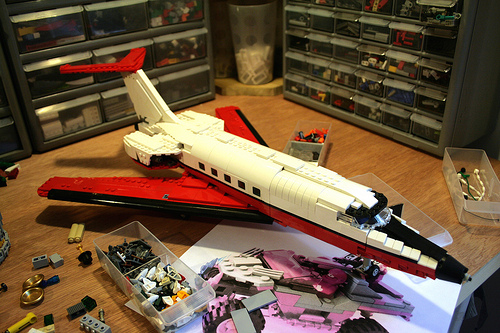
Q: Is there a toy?
A: Yes, there is a toy.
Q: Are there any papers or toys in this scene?
A: Yes, there is a toy.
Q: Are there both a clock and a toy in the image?
A: No, there is a toy but no clocks.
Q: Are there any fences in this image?
A: No, there are no fences.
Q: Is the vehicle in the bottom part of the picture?
A: Yes, the vehicle is in the bottom of the image.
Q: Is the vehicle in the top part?
A: No, the vehicle is in the bottom of the image.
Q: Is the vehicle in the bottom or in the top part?
A: The vehicle is in the bottom of the image.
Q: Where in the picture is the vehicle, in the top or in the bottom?
A: The vehicle is in the bottom of the image.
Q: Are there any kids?
A: No, there are no kids.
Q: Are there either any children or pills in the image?
A: No, there are no children or pills.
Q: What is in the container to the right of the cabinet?
A: The Lego is in the container.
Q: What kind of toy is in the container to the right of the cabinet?
A: The toy is a Lego.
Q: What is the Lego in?
A: The Lego is in the container.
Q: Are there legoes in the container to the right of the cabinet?
A: Yes, there is a Lego in the container.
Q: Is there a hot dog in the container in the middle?
A: No, there is a Lego in the container.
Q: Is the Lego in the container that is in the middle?
A: Yes, the Lego is in the container.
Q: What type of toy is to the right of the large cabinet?
A: The toy is a Lego.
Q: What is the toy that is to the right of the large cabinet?
A: The toy is a Lego.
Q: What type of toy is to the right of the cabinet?
A: The toy is a Lego.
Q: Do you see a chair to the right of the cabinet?
A: No, there is a Lego to the right of the cabinet.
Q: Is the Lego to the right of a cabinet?
A: Yes, the Lego is to the right of a cabinet.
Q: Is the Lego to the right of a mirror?
A: No, the Lego is to the right of a cabinet.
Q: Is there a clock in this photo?
A: No, there are no clocks.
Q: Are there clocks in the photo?
A: No, there are no clocks.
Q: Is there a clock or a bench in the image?
A: No, there are no clocks or benches.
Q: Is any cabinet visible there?
A: Yes, there is a cabinet.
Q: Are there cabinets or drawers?
A: Yes, there is a cabinet.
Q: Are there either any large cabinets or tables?
A: Yes, there is a large cabinet.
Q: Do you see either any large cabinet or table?
A: Yes, there is a large cabinet.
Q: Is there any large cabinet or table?
A: Yes, there is a large cabinet.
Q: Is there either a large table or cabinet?
A: Yes, there is a large cabinet.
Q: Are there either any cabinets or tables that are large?
A: Yes, the cabinet is large.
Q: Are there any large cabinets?
A: Yes, there is a large cabinet.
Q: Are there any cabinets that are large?
A: Yes, there is a cabinet that is large.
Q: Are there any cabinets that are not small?
A: Yes, there is a large cabinet.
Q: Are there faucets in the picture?
A: No, there are no faucets.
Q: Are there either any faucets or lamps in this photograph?
A: No, there are no faucets or lamps.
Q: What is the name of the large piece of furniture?
A: The piece of furniture is a cabinet.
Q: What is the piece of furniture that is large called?
A: The piece of furniture is a cabinet.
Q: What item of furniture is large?
A: The piece of furniture is a cabinet.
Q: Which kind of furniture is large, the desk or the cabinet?
A: The cabinet is large.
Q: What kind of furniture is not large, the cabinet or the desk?
A: The desk is not large.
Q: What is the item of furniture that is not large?
A: The piece of furniture is a desk.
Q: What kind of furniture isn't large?
A: The furniture is a desk.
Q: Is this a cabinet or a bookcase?
A: This is a cabinet.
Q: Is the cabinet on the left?
A: Yes, the cabinet is on the left of the image.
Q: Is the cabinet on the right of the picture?
A: No, the cabinet is on the left of the image.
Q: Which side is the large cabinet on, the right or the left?
A: The cabinet is on the left of the image.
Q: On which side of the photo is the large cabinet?
A: The cabinet is on the left of the image.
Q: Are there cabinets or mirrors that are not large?
A: No, there is a cabinet but it is large.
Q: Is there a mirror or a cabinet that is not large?
A: No, there is a cabinet but it is large.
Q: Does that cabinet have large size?
A: Yes, the cabinet is large.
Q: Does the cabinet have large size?
A: Yes, the cabinet is large.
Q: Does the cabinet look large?
A: Yes, the cabinet is large.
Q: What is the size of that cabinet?
A: The cabinet is large.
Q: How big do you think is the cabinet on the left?
A: The cabinet is large.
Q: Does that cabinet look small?
A: No, the cabinet is large.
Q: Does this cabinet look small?
A: No, the cabinet is large.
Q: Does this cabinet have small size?
A: No, the cabinet is large.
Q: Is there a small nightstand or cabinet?
A: No, there is a cabinet but it is large.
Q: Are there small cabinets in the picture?
A: No, there is a cabinet but it is large.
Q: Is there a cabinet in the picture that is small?
A: No, there is a cabinet but it is large.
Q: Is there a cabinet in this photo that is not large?
A: No, there is a cabinet but it is large.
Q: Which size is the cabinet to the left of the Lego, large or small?
A: The cabinet is large.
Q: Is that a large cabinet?
A: Yes, that is a large cabinet.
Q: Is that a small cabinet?
A: No, that is a large cabinet.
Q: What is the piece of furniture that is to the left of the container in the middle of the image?
A: The piece of furniture is a cabinet.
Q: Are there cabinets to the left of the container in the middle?
A: Yes, there is a cabinet to the left of the container.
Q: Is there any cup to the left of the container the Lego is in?
A: No, there is a cabinet to the left of the container.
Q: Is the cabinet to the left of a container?
A: Yes, the cabinet is to the left of a container.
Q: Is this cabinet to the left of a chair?
A: No, the cabinet is to the left of a container.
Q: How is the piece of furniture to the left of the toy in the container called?
A: The piece of furniture is a cabinet.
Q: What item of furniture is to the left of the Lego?
A: The piece of furniture is a cabinet.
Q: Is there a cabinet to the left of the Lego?
A: Yes, there is a cabinet to the left of the Lego.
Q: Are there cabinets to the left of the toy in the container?
A: Yes, there is a cabinet to the left of the Lego.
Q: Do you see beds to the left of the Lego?
A: No, there is a cabinet to the left of the Lego.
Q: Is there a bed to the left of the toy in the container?
A: No, there is a cabinet to the left of the Lego.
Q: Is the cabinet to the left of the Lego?
A: Yes, the cabinet is to the left of the Lego.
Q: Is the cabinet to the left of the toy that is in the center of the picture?
A: Yes, the cabinet is to the left of the Lego.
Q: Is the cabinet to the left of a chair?
A: No, the cabinet is to the left of the Lego.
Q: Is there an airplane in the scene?
A: Yes, there is an airplane.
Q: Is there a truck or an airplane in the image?
A: Yes, there is an airplane.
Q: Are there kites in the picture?
A: No, there are no kites.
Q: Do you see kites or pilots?
A: No, there are no kites or pilots.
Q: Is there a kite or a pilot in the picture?
A: No, there are no kites or pilots.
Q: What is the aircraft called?
A: The aircraft is an airplane.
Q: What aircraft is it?
A: The aircraft is an airplane.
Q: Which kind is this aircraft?
A: That is an airplane.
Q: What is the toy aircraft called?
A: The aircraft is an airplane.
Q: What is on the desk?
A: The airplane is on the desk.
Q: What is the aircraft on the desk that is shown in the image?
A: The aircraft is an airplane.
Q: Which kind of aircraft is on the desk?
A: The aircraft is an airplane.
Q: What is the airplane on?
A: The airplane is on the desk.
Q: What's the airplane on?
A: The airplane is on the desk.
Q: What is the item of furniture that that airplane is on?
A: The piece of furniture is a desk.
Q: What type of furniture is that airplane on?
A: The airplane is on the desk.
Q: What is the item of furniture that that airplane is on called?
A: The piece of furniture is a desk.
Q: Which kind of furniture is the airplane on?
A: The airplane is on the desk.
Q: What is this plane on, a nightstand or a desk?
A: The plane is on a desk.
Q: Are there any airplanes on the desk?
A: Yes, there is an airplane on the desk.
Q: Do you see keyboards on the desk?
A: No, there is an airplane on the desk.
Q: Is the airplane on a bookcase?
A: No, the airplane is on the desk.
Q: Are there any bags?
A: No, there are no bags.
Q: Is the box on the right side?
A: Yes, the box is on the right of the image.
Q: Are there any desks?
A: Yes, there is a desk.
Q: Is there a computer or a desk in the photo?
A: Yes, there is a desk.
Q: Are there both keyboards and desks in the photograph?
A: No, there is a desk but no keyboards.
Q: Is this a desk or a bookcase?
A: This is a desk.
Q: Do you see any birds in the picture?
A: No, there are no birds.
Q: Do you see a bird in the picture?
A: No, there are no birds.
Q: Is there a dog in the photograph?
A: No, there are no dogs.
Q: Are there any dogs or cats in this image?
A: No, there are no dogs or cats.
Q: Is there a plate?
A: No, there are no plates.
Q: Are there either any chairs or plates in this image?
A: No, there are no plates or chairs.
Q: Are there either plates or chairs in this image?
A: No, there are no plates or chairs.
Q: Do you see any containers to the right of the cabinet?
A: Yes, there is a container to the right of the cabinet.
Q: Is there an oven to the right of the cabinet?
A: No, there is a container to the right of the cabinet.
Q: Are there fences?
A: No, there are no fences.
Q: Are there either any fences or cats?
A: No, there are no fences or cats.